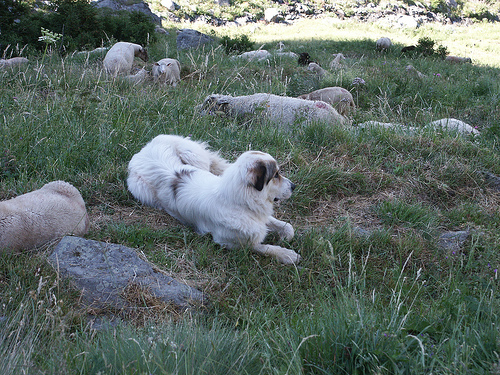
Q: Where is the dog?
A: On the grass.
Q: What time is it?
A: Afternoon.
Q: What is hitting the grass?
A: Light.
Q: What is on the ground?
A: Rocks.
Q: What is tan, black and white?
A: The dog.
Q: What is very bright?
A: Top of the picture.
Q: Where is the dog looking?
A: To the right.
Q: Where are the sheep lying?
A: In the grass.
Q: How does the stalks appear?
A: Tall.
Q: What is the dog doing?
A: Laying down.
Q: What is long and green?
A: Grass.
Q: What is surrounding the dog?
A: Sheep.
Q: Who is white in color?
A: The dog.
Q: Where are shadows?
A: On the grass.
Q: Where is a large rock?
A: On the grass.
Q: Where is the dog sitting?
A: On grass.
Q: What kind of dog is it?
A: Sheep dog.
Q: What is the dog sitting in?
A: Grass.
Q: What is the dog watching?
A: Sheep.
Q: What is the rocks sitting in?
A: Grass.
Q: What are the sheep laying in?
A: Grass.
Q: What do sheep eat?
A: Grass.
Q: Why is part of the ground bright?
A: Sunny.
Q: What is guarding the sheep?
A: Dog.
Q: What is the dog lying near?
A: Rock.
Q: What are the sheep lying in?
A: Field.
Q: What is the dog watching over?
A: Sheep.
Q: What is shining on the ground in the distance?
A: Sunshine.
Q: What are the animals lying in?
A: A field.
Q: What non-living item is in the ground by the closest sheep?
A: A rock.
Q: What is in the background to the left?
A: Trees.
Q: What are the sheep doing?
A: Laying down.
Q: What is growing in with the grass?
A: Weeds.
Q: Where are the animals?
A: In a pasture.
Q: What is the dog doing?
A: Laying down.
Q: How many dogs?
A: 1.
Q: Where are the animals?
A: Ground.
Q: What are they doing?
A: Resting.